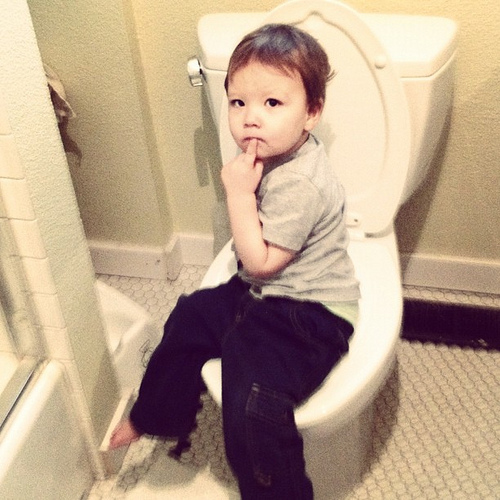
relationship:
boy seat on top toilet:
[87, 13, 380, 499] [341, 2, 450, 476]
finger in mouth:
[239, 129, 262, 163] [240, 132, 268, 146]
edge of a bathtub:
[2, 220, 50, 418] [0, 4, 109, 498]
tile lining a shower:
[3, 0, 112, 426] [0, 4, 109, 498]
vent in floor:
[402, 290, 500, 355] [384, 356, 500, 498]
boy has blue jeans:
[87, 13, 380, 499] [122, 278, 359, 500]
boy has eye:
[87, 13, 380, 499] [227, 92, 289, 113]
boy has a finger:
[87, 13, 380, 499] [239, 129, 262, 163]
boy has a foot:
[87, 13, 380, 499] [100, 407, 144, 455]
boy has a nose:
[87, 13, 380, 499] [242, 101, 263, 129]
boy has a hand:
[87, 13, 380, 499] [216, 137, 267, 198]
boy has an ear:
[87, 13, 380, 499] [301, 90, 329, 133]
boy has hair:
[87, 13, 380, 499] [206, 16, 338, 119]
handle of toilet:
[181, 52, 210, 95] [341, 2, 450, 476]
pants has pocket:
[122, 278, 359, 500] [284, 298, 349, 349]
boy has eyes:
[87, 13, 380, 499] [227, 92, 289, 113]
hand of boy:
[216, 137, 267, 198] [87, 13, 380, 499]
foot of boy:
[100, 407, 144, 455] [87, 13, 380, 499]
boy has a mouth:
[87, 13, 380, 499] [240, 132, 268, 146]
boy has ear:
[87, 13, 380, 499] [301, 90, 329, 133]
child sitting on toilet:
[87, 13, 380, 499] [341, 2, 450, 476]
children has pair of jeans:
[96, 15, 367, 500] [122, 278, 359, 500]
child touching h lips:
[87, 13, 380, 499] [240, 132, 268, 146]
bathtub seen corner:
[0, 4, 109, 498] [2, 220, 50, 418]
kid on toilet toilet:
[87, 13, 380, 499] [341, 2, 450, 476]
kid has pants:
[87, 13, 380, 499] [122, 278, 359, 500]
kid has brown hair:
[87, 13, 380, 499] [206, 16, 338, 119]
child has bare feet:
[87, 13, 380, 499] [100, 407, 144, 455]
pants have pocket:
[122, 278, 359, 500] [284, 298, 349, 349]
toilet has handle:
[341, 2, 450, 476] [181, 52, 210, 95]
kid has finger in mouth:
[87, 13, 380, 499] [240, 132, 268, 146]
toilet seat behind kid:
[317, 4, 419, 238] [87, 13, 380, 499]